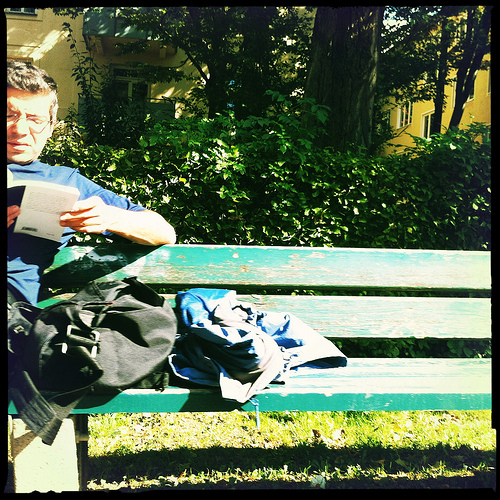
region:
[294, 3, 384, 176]
Trunk of a tree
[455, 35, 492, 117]
Trunk of a tree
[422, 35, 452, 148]
Trunk of a tree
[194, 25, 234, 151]
Trunk of a tree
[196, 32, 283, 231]
Trunk of a tree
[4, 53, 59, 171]
Head of a person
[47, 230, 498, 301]
a rail of a wood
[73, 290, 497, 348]
a rail of a wood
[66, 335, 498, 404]
a rail of a wood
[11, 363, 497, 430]
a rail of a wood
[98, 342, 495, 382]
a rail of a wood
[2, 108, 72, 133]
glasses on man's face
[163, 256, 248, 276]
chipped paint on bench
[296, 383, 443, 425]
blue color on bench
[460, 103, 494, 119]
yellow paint on the wall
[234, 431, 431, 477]
bench's shadow on the ground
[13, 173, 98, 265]
white paper in man's hand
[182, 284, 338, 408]
jacket on blue bench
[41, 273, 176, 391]
green bag on bench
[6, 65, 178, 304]
man sitting on bench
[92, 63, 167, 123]
window in yellow house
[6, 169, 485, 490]
this is a bench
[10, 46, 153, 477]
this is a man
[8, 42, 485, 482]
man sitting in a bench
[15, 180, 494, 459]
the bench is green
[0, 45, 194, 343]
man is reading a book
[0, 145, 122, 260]
this is a book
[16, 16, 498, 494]
a bright and sunny day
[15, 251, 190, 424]
this is a bag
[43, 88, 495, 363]
bushes in the background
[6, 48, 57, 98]
man has brown hair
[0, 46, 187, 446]
Man sitting on a bench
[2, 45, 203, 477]
The man is reading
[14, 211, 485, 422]
Bench made out of wood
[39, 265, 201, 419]
Black bag next to the man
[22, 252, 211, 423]
Black bag on the bench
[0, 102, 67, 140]
Glasses on the man's face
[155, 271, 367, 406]
A jacket on the bench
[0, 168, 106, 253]
Book in the man's hands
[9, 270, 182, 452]
a backpack color black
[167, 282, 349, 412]
a shirt is color blue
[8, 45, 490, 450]
man sit on a green bench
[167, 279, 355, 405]
A shirt on the bench.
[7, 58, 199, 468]
A man sitting on the bench.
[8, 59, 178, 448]
A man reading a book.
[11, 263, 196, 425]
A black backpack on the bench.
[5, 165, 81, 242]
book is open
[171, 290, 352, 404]
jacket is on the bench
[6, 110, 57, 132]
glasses are on the mans face